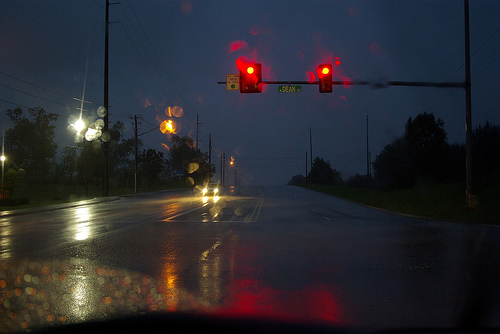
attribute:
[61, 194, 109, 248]
light — white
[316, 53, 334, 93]
traffic light — on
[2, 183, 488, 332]
road — shiny, wet, asphalt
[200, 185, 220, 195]
headlights — on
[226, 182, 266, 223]
lines — yellow 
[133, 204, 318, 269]
street — paved 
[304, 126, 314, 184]
pole — wood , electrical 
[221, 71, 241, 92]
sign — white 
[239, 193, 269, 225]
line — double , yellow 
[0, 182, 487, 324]
ground — wet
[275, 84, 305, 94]
sign — green, white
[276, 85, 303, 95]
road sign — green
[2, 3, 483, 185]
sky — dark, dark blue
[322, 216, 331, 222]
line — white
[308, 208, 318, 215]
line — white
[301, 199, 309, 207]
line — white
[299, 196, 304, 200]
line — white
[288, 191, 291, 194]
line — white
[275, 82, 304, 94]
street sign — white, green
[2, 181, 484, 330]
roadway — wet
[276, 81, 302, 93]
street sign — green, white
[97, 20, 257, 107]
skies — dark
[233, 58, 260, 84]
light — red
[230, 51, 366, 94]
lights — red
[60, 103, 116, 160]
street light — lit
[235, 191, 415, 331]
road — clear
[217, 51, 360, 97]
light — red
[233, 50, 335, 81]
light — blurry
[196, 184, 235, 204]
lights — on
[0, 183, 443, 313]
road — wet, concrete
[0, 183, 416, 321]
road — concrete, wet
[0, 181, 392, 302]
road — wet, concrete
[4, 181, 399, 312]
road — concrete, wet